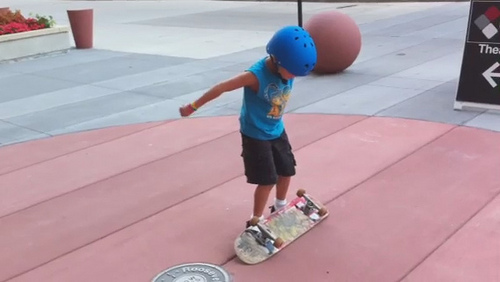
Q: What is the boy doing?
A: Skateboarding.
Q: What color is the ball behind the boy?
A: Red.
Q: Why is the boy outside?
A: Playing.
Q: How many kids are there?
A: 1.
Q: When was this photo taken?
A: Daytime.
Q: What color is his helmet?
A: Blue.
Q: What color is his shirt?
A: Blue.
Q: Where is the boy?
A: On the boardwalk.